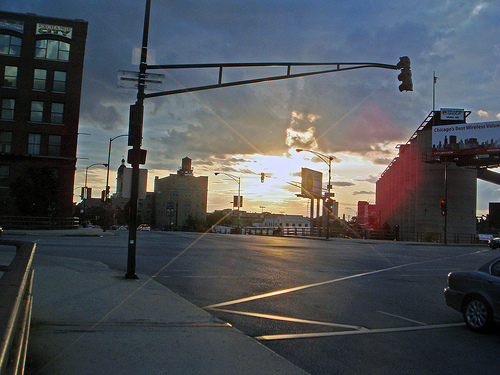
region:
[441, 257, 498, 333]
car on paved empty street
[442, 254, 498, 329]
the car is a sedan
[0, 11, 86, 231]
tall brick building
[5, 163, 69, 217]
bush in front of building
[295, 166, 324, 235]
billboard against sky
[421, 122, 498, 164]
billboard near traffic light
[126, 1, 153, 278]
tall black metal pole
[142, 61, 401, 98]
black metal arm over street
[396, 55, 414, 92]
traffic light over street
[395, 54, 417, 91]
traffic light attached to long arm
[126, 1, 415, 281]
street light overlooking street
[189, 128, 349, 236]
lightposts in background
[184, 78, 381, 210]
sun shining through clouds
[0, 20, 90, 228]
dark warehouse with windows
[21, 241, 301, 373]
sidewalk next to road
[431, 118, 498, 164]
white and red billboard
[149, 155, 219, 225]
water tower on building in distance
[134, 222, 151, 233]
car in distance with red brake lights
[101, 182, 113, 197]
stoplight in distance with green light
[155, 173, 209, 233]
tan old building in distance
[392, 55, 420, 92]
back of traffic light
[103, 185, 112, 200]
traffic light indicating green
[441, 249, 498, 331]
rear of car driving on street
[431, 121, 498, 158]
large advertising sign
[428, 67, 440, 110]
flagpole on top of building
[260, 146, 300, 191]
sun setting behind clouds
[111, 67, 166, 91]
back of street sign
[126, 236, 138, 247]
button for cross walk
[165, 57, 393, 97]
black metal traffic light supports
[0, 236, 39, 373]
silver metal guard rail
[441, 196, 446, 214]
traffic light on a red signal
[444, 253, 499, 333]
gray vehicle on the street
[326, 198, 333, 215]
traffic light with a green signal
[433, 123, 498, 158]
large billboard with red print on it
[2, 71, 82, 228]
nine windows on a brick building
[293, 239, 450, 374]
gray street with white lines going across it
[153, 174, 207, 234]
tall peach colored building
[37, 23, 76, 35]
green CITY text on a white sign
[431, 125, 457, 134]
red print reading Chicago's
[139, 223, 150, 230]
red lights on a white vehicle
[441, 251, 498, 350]
The dark gray car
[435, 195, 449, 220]
The red street lights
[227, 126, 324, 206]
The sun shining through the clouds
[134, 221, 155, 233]
The tail lights of a car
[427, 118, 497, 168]
The billboard above the red street light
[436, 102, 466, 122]
The sign on the building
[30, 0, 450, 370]
The x made from the sun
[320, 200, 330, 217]
The green street light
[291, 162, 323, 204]
The billboard above the green street light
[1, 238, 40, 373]
The railing on the sidewalk